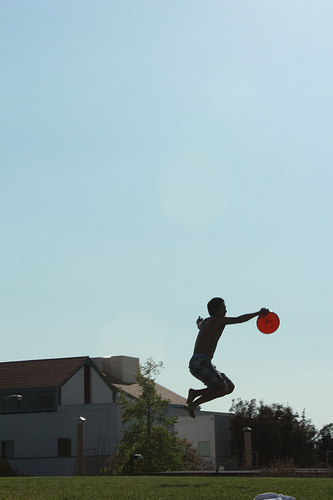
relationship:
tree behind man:
[100, 358, 191, 473] [184, 296, 269, 416]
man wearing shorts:
[184, 296, 269, 416] [188, 354, 232, 388]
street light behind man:
[1, 393, 23, 403] [184, 296, 269, 416]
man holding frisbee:
[184, 296, 269, 416] [256, 311, 280, 334]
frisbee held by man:
[256, 311, 280, 334] [184, 296, 269, 416]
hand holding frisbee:
[258, 306, 271, 317] [256, 311, 280, 334]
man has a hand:
[184, 296, 269, 416] [258, 306, 271, 317]